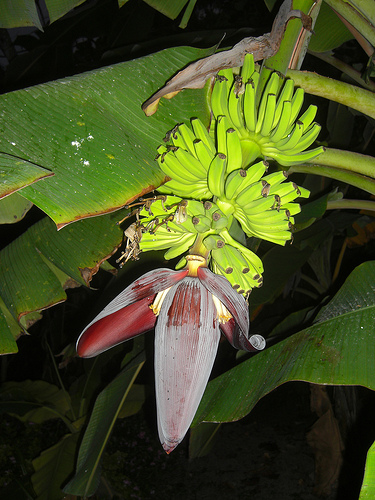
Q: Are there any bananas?
A: Yes, there is a banana.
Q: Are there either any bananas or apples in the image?
A: Yes, there is a banana.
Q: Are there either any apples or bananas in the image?
A: Yes, there is a banana.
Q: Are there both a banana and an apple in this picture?
A: No, there is a banana but no apples.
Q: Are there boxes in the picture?
A: No, there are no boxes.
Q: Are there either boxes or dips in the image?
A: No, there are no boxes or dips.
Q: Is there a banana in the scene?
A: Yes, there is a banana.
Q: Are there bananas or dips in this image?
A: Yes, there is a banana.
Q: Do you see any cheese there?
A: No, there is no cheese.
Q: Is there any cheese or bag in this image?
A: No, there are no cheese or bags.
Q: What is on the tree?
A: The banana is on the tree.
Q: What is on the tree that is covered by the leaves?
A: The banana is on the tree.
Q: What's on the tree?
A: The banana is on the tree.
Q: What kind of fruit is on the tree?
A: The fruit is a banana.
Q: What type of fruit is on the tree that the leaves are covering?
A: The fruit is a banana.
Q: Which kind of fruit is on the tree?
A: The fruit is a banana.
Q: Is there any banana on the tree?
A: Yes, there is a banana on the tree.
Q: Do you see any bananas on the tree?
A: Yes, there is a banana on the tree.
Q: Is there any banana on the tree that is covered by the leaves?
A: Yes, there is a banana on the tree.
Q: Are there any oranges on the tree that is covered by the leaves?
A: No, there is a banana on the tree.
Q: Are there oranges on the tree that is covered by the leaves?
A: No, there is a banana on the tree.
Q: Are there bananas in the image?
A: Yes, there is a banana.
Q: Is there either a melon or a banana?
A: Yes, there is a banana.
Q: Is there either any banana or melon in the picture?
A: Yes, there is a banana.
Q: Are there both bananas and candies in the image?
A: No, there is a banana but no candies.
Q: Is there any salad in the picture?
A: No, there is no salad.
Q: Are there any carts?
A: No, there are no carts.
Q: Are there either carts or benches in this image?
A: No, there are no carts or benches.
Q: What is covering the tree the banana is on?
A: The leaves are covering the tree.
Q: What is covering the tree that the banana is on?
A: The leaves are covering the tree.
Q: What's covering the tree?
A: The leaves are covering the tree.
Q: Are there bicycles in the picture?
A: No, there are no bicycles.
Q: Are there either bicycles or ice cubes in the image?
A: No, there are no bicycles or ice cubes.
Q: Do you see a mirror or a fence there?
A: No, there are no fences or mirrors.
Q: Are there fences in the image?
A: No, there are no fences.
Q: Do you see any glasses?
A: No, there are no glasses.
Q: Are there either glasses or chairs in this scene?
A: No, there are no glasses or chairs.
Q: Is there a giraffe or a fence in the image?
A: No, there are no fences or giraffes.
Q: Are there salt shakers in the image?
A: No, there are no salt shakers.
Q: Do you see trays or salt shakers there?
A: No, there are no salt shakers or trays.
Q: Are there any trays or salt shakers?
A: No, there are no salt shakers or trays.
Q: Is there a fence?
A: No, there are no fences.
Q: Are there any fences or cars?
A: No, there are no fences or cars.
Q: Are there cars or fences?
A: No, there are no fences or cars.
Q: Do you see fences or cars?
A: No, there are no fences or cars.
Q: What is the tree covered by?
A: The tree is covered by the leaves.